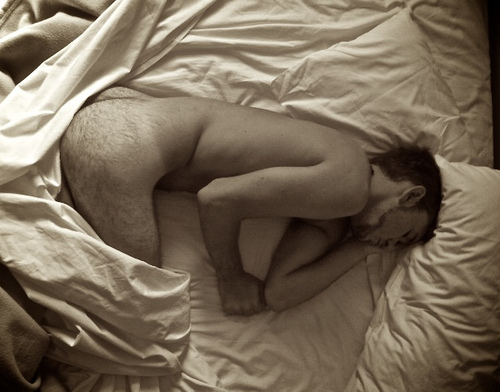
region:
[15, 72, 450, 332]
A naked sleeping man in bed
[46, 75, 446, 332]
A naked sleeping man in bed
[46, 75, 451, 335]
A naked sleeping man in bed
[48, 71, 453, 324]
A naked sleeping man in bed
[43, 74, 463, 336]
A naked sleeping man in bed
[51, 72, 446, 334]
A naked sleeping man in bed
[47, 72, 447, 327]
A naked sleeping man in bed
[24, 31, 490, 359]
a naked man in bed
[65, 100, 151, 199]
hair on the butt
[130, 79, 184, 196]
a tan line across waist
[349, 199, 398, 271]
a beard on face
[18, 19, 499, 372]
white sheets on bed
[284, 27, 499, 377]
two large white pillows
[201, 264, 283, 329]
a hand by the elbow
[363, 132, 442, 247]
dark hair on head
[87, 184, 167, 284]
a hairy thigh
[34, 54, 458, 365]
a sleeping naked man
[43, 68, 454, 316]
a naked man sleeping in a bed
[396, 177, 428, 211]
the ear of a man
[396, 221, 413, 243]
the eye of a man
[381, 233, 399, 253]
the nose of a man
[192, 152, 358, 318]
the arms of a man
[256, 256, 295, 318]
the elbow of a man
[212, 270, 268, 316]
the hand of a man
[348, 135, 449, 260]
the head of a man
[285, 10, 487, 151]
a white pillow on a bed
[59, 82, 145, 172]
a hairy butte of a man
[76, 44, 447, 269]
man laying nude on bed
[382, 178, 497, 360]
white pillow near head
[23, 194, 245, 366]
white sheet covering leg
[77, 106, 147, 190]
long hair growing around buttocks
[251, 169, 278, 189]
small moles on man's arm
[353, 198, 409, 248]
facial hair growing on man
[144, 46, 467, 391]
white sheet under man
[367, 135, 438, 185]
dark hair on man's head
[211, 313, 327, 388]
wrinkles in a white sheet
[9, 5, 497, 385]
naked man in bed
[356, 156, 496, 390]
pillow on top of bed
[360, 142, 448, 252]
head pushing under pillow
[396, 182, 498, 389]
wrinkles in pillow case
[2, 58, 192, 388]
sheets and blanket pulled down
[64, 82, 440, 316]
naked man on sheets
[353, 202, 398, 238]
trimmed beard on face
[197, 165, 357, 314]
arms bent at elbow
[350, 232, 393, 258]
hand under man's face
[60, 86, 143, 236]
hair on man's buttocks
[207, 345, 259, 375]
A wrinkle in the sheets.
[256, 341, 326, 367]
A wrinkle in the sheets.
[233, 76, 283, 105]
A wrinkle in the sheets.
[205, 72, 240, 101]
A wrinkle in the sheets.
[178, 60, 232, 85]
A wrinkle in the sheets.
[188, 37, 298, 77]
A wrinkle in the sheets.